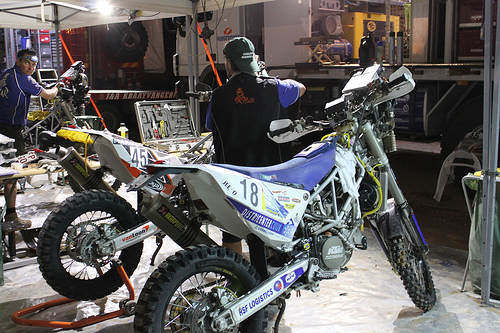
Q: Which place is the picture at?
A: It is at the garage.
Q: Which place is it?
A: It is a garage.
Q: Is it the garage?
A: Yes, it is the garage.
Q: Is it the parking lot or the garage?
A: It is the garage.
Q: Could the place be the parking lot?
A: No, it is the garage.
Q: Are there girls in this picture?
A: No, there are no girls.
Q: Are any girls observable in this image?
A: No, there are no girls.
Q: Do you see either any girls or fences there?
A: No, there are no girls or fences.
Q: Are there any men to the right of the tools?
A: Yes, there is a man to the right of the tools.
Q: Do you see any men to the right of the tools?
A: Yes, there is a man to the right of the tools.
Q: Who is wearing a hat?
A: The man is wearing a hat.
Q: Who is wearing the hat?
A: The man is wearing a hat.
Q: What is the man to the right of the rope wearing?
A: The man is wearing a hat.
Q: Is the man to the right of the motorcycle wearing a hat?
A: Yes, the man is wearing a hat.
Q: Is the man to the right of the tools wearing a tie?
A: No, the man is wearing a hat.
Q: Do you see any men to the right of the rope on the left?
A: Yes, there is a man to the right of the rope.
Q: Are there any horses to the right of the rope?
A: No, there is a man to the right of the rope.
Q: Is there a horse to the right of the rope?
A: No, there is a man to the right of the rope.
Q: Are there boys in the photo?
A: No, there are no boys.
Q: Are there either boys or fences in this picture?
A: No, there are no boys or fences.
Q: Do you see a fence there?
A: No, there are no fences.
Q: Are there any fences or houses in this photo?
A: No, there are no fences or houses.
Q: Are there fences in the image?
A: No, there are no fences.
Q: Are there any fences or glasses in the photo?
A: No, there are no fences or glasses.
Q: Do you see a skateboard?
A: No, there are no skateboards.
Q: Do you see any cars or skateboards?
A: No, there are no skateboards or cars.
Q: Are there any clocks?
A: No, there are no clocks.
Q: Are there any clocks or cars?
A: No, there are no clocks or cars.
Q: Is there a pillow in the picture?
A: No, there are no pillows.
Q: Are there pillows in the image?
A: No, there are no pillows.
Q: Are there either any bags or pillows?
A: No, there are no pillows or bags.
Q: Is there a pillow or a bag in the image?
A: No, there are no pillows or bags.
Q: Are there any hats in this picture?
A: Yes, there is a hat.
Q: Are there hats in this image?
A: Yes, there is a hat.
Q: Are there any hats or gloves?
A: Yes, there is a hat.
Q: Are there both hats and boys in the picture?
A: No, there is a hat but no boys.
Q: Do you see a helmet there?
A: No, there are no helmets.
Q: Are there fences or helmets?
A: No, there are no helmets or fences.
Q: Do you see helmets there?
A: No, there are no helmets.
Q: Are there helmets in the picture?
A: No, there are no helmets.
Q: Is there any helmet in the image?
A: No, there are no helmets.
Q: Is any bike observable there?
A: Yes, there is a bike.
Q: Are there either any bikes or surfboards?
A: Yes, there is a bike.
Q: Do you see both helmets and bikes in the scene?
A: No, there is a bike but no helmets.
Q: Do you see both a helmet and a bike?
A: No, there is a bike but no helmets.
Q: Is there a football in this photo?
A: No, there are no footballs.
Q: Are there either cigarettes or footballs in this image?
A: No, there are no footballs or cigarettes.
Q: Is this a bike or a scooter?
A: This is a bike.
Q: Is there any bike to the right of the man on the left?
A: Yes, there is a bike to the right of the man.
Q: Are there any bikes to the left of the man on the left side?
A: No, the bike is to the right of the man.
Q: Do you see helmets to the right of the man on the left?
A: No, there is a bike to the right of the man.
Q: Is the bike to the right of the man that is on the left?
A: Yes, the bike is to the right of the man.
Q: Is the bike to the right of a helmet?
A: No, the bike is to the right of the man.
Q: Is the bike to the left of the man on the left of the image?
A: No, the bike is to the right of the man.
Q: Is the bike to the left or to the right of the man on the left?
A: The bike is to the right of the man.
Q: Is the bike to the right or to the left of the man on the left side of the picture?
A: The bike is to the right of the man.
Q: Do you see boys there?
A: No, there are no boys.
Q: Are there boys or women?
A: No, there are no boys or women.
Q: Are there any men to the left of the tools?
A: Yes, there is a man to the left of the tools.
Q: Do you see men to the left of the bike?
A: Yes, there is a man to the left of the bike.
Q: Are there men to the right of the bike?
A: No, the man is to the left of the bike.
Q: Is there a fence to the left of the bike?
A: No, there is a man to the left of the bike.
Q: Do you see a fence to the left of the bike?
A: No, there is a man to the left of the bike.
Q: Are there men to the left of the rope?
A: Yes, there is a man to the left of the rope.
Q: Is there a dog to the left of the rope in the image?
A: No, there is a man to the left of the rope.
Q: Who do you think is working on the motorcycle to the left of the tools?
A: The man is working on the motorbike.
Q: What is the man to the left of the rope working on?
A: The man is working on the motorcycle.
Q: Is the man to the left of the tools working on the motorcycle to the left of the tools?
A: Yes, the man is working on the motorbike.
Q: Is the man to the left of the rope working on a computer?
A: No, the man is working on the motorbike.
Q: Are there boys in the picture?
A: No, there are no boys.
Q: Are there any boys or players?
A: No, there are no boys or players.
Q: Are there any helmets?
A: No, there are no helmets.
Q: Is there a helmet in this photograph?
A: No, there are no helmets.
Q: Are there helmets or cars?
A: No, there are no helmets or cars.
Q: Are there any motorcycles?
A: Yes, there is a motorcycle.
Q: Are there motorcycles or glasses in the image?
A: Yes, there is a motorcycle.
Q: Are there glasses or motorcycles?
A: Yes, there is a motorcycle.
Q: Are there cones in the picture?
A: No, there are no cones.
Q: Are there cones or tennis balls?
A: No, there are no cones or tennis balls.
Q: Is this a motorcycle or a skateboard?
A: This is a motorcycle.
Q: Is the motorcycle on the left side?
A: Yes, the motorcycle is on the left of the image.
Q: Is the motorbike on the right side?
A: No, the motorbike is on the left of the image.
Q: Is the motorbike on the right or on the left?
A: The motorbike is on the left of the image.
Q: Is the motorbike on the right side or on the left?
A: The motorbike is on the left of the image.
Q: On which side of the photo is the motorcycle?
A: The motorcycle is on the left of the image.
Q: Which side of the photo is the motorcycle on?
A: The motorcycle is on the left of the image.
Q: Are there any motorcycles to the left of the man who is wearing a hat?
A: Yes, there is a motorcycle to the left of the man.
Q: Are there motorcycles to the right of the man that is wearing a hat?
A: No, the motorcycle is to the left of the man.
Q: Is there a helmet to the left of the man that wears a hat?
A: No, there is a motorcycle to the left of the man.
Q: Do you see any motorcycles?
A: Yes, there is a motorcycle.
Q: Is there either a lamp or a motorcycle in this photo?
A: Yes, there is a motorcycle.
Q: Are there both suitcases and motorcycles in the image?
A: No, there is a motorcycle but no suitcases.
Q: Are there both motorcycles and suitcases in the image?
A: No, there is a motorcycle but no suitcases.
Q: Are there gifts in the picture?
A: No, there are no gifts.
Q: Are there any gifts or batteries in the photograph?
A: No, there are no gifts or batteries.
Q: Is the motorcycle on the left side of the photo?
A: Yes, the motorcycle is on the left of the image.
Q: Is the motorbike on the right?
A: No, the motorbike is on the left of the image.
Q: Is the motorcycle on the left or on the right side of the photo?
A: The motorcycle is on the left of the image.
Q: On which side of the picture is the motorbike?
A: The motorbike is on the left of the image.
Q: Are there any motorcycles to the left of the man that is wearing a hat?
A: Yes, there is a motorcycle to the left of the man.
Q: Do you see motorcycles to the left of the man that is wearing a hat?
A: Yes, there is a motorcycle to the left of the man.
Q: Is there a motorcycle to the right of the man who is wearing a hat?
A: No, the motorcycle is to the left of the man.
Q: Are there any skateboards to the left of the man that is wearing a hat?
A: No, there is a motorcycle to the left of the man.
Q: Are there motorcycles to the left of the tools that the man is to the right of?
A: Yes, there is a motorcycle to the left of the tools.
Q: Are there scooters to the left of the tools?
A: No, there is a motorcycle to the left of the tools.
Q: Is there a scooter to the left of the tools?
A: No, there is a motorcycle to the left of the tools.